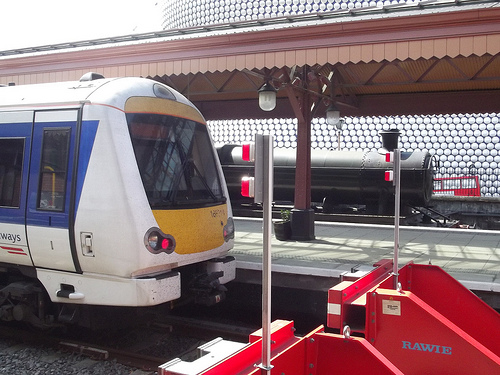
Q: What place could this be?
A: It is a station.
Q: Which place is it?
A: It is a station.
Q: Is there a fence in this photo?
A: No, there are no fences.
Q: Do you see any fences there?
A: No, there are no fences.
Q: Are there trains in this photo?
A: Yes, there is a train.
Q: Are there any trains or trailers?
A: Yes, there is a train.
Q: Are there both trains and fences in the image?
A: No, there is a train but no fences.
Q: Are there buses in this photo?
A: No, there are no buses.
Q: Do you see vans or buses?
A: No, there are no buses or vans.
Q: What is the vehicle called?
A: The vehicle is a train.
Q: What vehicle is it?
A: The vehicle is a train.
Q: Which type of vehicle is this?
A: This is a train.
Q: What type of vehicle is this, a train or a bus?
A: This is a train.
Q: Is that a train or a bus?
A: That is a train.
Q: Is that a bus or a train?
A: That is a train.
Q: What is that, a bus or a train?
A: That is a train.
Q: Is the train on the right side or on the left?
A: The train is on the left of the image.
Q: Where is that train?
A: The train is at the station.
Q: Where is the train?
A: The train is at the station.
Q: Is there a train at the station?
A: Yes, there is a train at the station.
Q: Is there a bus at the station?
A: No, there is a train at the station.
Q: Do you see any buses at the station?
A: No, there is a train at the station.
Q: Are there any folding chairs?
A: No, there are no folding chairs.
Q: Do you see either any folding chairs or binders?
A: No, there are no folding chairs or binders.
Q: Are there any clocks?
A: No, there are no clocks.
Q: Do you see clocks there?
A: No, there are no clocks.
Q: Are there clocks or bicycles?
A: No, there are no clocks or bicycles.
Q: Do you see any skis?
A: No, there are no skis.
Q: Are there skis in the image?
A: No, there are no skis.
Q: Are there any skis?
A: No, there are no skis.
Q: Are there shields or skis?
A: No, there are no skis or shields.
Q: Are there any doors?
A: Yes, there is a door.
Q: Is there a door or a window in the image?
A: Yes, there is a door.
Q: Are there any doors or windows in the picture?
A: Yes, there is a door.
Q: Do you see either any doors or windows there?
A: Yes, there is a door.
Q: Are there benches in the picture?
A: No, there are no benches.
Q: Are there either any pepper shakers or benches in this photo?
A: No, there are no benches or pepper shakers.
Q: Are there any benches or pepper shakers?
A: No, there are no benches or pepper shakers.